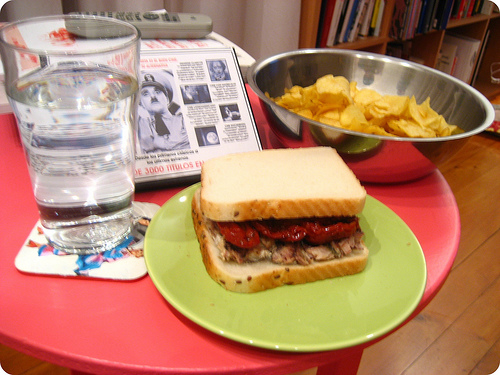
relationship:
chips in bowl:
[276, 65, 445, 140] [249, 41, 494, 181]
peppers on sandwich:
[216, 216, 360, 245] [193, 142, 368, 300]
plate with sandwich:
[138, 180, 429, 353] [193, 142, 368, 300]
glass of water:
[11, 18, 151, 252] [12, 74, 129, 235]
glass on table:
[11, 18, 151, 252] [2, 60, 466, 374]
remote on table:
[66, 4, 221, 38] [2, 60, 466, 374]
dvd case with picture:
[79, 37, 265, 194] [139, 67, 186, 150]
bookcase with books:
[302, 4, 499, 96] [320, 4, 490, 94]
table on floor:
[2, 60, 466, 374] [361, 128, 498, 373]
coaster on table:
[19, 198, 161, 284] [2, 60, 466, 374]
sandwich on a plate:
[193, 142, 368, 300] [138, 180, 429, 353]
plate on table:
[138, 180, 429, 353] [2, 60, 466, 374]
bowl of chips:
[249, 41, 494, 181] [276, 65, 445, 140]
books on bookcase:
[320, 4, 490, 94] [302, 4, 499, 96]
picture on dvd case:
[139, 67, 186, 150] [79, 37, 265, 194]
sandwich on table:
[193, 142, 368, 300] [2, 60, 466, 374]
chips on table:
[276, 65, 445, 140] [2, 60, 466, 374]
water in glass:
[12, 74, 129, 235] [11, 18, 151, 252]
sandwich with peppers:
[193, 142, 368, 300] [216, 216, 360, 245]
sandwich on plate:
[193, 142, 368, 300] [138, 180, 429, 353]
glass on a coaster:
[11, 18, 151, 252] [19, 198, 161, 284]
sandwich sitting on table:
[193, 142, 368, 300] [2, 60, 466, 374]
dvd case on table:
[79, 37, 265, 194] [2, 60, 466, 374]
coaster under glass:
[19, 198, 161, 284] [11, 18, 151, 252]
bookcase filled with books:
[302, 4, 499, 96] [320, 4, 490, 94]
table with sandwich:
[2, 60, 466, 374] [193, 142, 368, 300]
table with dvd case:
[2, 60, 466, 374] [79, 37, 265, 194]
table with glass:
[2, 60, 466, 374] [11, 18, 151, 252]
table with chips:
[2, 60, 466, 374] [276, 65, 445, 140]